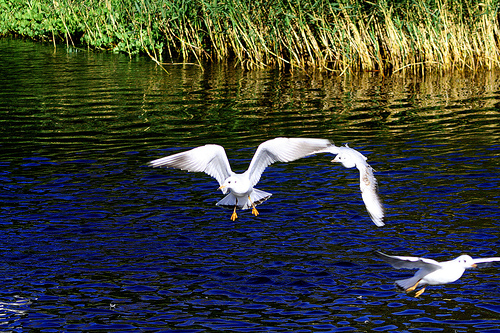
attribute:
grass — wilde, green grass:
[2, 3, 492, 70]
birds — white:
[153, 127, 333, 221]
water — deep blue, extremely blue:
[1, 28, 495, 324]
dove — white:
[373, 247, 499, 299]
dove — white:
[309, 144, 387, 229]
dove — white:
[148, 134, 338, 221]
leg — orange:
[223, 204, 243, 224]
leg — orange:
[245, 200, 261, 219]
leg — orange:
[399, 282, 419, 294]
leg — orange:
[413, 288, 430, 302]